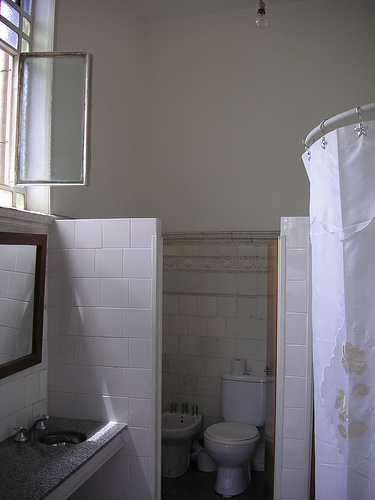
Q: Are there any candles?
A: No, there are no candles.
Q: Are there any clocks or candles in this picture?
A: No, there are no candles or clocks.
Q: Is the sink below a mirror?
A: Yes, the sink is below a mirror.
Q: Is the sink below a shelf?
A: No, the sink is below a mirror.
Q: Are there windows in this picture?
A: Yes, there is a window.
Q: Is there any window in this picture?
A: Yes, there is a window.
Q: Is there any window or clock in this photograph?
A: Yes, there is a window.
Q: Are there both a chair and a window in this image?
A: No, there is a window but no chairs.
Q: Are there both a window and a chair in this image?
A: No, there is a window but no chairs.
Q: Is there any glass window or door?
A: Yes, there is a glass window.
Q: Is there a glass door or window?
A: Yes, there is a glass window.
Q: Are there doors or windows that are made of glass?
A: Yes, the window is made of glass.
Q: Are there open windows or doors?
A: Yes, there is an open window.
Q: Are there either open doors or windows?
A: Yes, there is an open window.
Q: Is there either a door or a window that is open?
A: Yes, the window is open.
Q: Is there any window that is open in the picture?
A: Yes, there is an open window.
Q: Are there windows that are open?
A: Yes, there is a window that is open.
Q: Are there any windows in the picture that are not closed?
A: Yes, there is a open window.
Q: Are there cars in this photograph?
A: No, there are no cars.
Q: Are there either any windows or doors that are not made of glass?
A: No, there is a window but it is made of glass.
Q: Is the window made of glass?
A: Yes, the window is made of glass.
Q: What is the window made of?
A: The window is made of glass.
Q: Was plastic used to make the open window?
A: No, the window is made of glass.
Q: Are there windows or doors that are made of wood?
A: No, there is a window but it is made of glass.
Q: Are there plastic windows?
A: No, there is a window but it is made of glass.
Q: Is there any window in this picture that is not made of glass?
A: No, there is a window but it is made of glass.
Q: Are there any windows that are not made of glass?
A: No, there is a window but it is made of glass.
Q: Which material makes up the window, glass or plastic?
A: The window is made of glass.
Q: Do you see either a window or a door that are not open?
A: No, there is a window but it is open.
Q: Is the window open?
A: Yes, the window is open.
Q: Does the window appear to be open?
A: Yes, the window is open.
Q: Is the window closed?
A: No, the window is open.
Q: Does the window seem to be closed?
A: No, the window is open.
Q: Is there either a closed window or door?
A: No, there is a window but it is open.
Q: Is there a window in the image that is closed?
A: No, there is a window but it is open.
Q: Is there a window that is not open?
A: No, there is a window but it is open.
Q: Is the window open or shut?
A: The window is open.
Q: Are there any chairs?
A: No, there are no chairs.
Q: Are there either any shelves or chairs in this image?
A: No, there are no chairs or shelves.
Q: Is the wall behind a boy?
A: No, the wall is behind the toilet.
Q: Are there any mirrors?
A: Yes, there is a mirror.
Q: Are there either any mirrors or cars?
A: Yes, there is a mirror.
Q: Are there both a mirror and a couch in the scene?
A: No, there is a mirror but no couches.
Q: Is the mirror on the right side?
A: No, the mirror is on the left of the image.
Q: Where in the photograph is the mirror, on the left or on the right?
A: The mirror is on the left of the image.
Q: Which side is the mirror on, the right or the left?
A: The mirror is on the left of the image.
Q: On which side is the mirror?
A: The mirror is on the left of the image.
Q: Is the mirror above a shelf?
A: No, the mirror is above a sink.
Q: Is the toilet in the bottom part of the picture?
A: Yes, the toilet is in the bottom of the image.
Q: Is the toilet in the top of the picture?
A: No, the toilet is in the bottom of the image.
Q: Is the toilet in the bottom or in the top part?
A: The toilet is in the bottom of the image.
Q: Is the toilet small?
A: Yes, the toilet is small.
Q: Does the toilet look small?
A: Yes, the toilet is small.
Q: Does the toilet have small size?
A: Yes, the toilet is small.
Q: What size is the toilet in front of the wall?
A: The toilet is small.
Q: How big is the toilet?
A: The toilet is small.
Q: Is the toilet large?
A: No, the toilet is small.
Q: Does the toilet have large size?
A: No, the toilet is small.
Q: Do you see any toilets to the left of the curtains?
A: Yes, there is a toilet to the left of the curtains.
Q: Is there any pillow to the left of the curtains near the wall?
A: No, there is a toilet to the left of the curtains.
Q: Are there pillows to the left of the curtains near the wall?
A: No, there is a toilet to the left of the curtains.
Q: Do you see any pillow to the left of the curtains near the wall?
A: No, there is a toilet to the left of the curtains.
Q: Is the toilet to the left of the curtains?
A: Yes, the toilet is to the left of the curtains.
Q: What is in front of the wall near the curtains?
A: The toilet is in front of the wall.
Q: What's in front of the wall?
A: The toilet is in front of the wall.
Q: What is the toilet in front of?
A: The toilet is in front of the wall.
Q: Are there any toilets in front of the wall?
A: Yes, there is a toilet in front of the wall.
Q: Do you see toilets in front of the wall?
A: Yes, there is a toilet in front of the wall.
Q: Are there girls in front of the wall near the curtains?
A: No, there is a toilet in front of the wall.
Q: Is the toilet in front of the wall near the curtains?
A: Yes, the toilet is in front of the wall.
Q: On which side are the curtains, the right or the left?
A: The curtains are on the right of the image.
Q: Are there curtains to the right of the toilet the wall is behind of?
A: Yes, there are curtains to the right of the toilet.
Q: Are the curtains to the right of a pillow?
A: No, the curtains are to the right of a toilet.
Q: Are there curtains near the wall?
A: Yes, there are curtains near the wall.